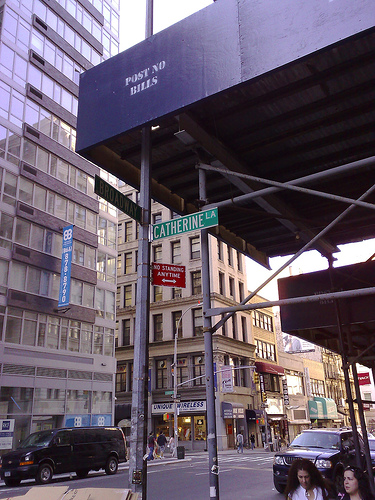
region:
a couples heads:
[278, 456, 370, 494]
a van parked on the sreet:
[6, 413, 126, 483]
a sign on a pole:
[136, 253, 195, 294]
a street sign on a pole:
[134, 202, 222, 250]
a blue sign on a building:
[51, 221, 79, 314]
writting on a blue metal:
[124, 50, 185, 110]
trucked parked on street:
[270, 429, 372, 486]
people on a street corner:
[139, 422, 194, 469]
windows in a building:
[1, 313, 113, 352]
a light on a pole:
[221, 360, 257, 377]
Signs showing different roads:
[102, 160, 224, 343]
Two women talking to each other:
[271, 436, 370, 494]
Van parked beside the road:
[3, 418, 146, 476]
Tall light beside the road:
[166, 320, 246, 466]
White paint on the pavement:
[226, 443, 281, 488]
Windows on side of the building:
[153, 306, 255, 413]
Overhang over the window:
[245, 348, 296, 386]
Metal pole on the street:
[199, 310, 233, 498]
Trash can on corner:
[173, 443, 190, 463]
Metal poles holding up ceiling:
[326, 318, 372, 419]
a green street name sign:
[151, 203, 220, 241]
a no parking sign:
[149, 261, 187, 291]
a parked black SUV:
[0, 426, 128, 480]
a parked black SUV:
[271, 426, 367, 492]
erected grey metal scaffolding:
[196, 156, 373, 497]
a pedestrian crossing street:
[234, 433, 244, 452]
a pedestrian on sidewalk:
[282, 459, 325, 499]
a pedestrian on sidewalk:
[330, 466, 371, 499]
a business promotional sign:
[57, 221, 73, 311]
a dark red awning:
[255, 358, 283, 377]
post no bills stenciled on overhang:
[115, 55, 174, 93]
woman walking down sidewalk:
[280, 458, 371, 498]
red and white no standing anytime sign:
[145, 258, 191, 291]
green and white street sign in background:
[160, 388, 175, 398]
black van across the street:
[7, 416, 130, 489]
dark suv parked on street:
[267, 415, 363, 493]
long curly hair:
[276, 454, 326, 495]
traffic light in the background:
[250, 364, 261, 394]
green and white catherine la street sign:
[138, 203, 223, 244]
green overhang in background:
[308, 394, 341, 421]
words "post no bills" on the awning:
[121, 56, 169, 104]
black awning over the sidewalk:
[76, 0, 374, 278]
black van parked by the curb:
[0, 422, 130, 484]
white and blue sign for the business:
[150, 396, 208, 419]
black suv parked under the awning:
[269, 421, 369, 493]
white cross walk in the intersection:
[181, 444, 282, 465]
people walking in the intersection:
[143, 428, 246, 462]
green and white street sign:
[164, 389, 177, 399]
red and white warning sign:
[141, 261, 190, 295]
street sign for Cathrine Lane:
[145, 203, 222, 247]